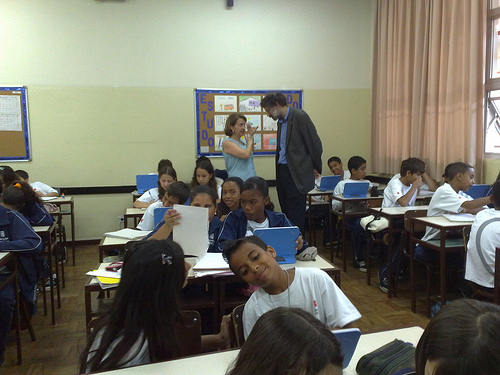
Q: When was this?
A: Daytime.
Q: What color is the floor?
A: Brown.